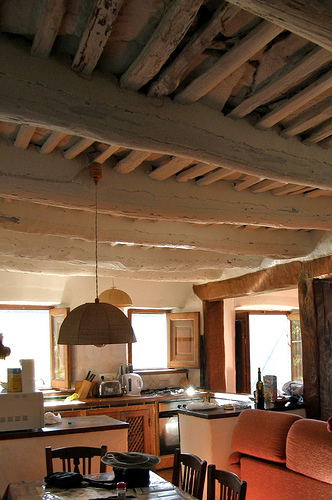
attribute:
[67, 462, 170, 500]
table — brown, below, wood, black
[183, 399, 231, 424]
counter — black, here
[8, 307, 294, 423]
kitchen — here, messy, small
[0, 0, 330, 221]
ceiling — brown, high, heavy, tall, black, wood, log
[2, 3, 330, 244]
logs — brown, wood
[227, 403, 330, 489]
cushions — curved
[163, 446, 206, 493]
chair — dark brown